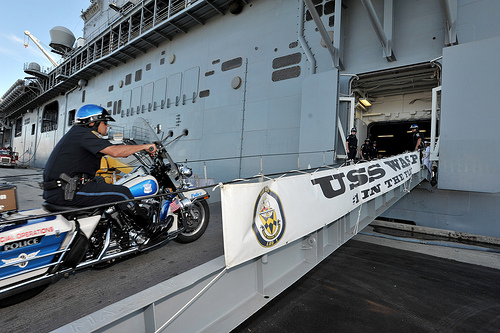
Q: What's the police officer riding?
A: Motorcycle.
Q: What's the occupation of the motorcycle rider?
A: Police officer.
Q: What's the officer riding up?
A: Ramp.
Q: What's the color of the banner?
A: White.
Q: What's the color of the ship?
A: Gray.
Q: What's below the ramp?
A: Water.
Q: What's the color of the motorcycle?
A: Blue and white.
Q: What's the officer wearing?
A: Uniform.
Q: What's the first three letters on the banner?
A: USS.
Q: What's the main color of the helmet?
A: Blue.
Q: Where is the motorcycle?
A: On bridge.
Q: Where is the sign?
A: Bridge's rail.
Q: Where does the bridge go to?
A: Ship.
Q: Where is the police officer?
A: On motorcycle.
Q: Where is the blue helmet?
A: On police officer.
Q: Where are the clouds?
A: Sky.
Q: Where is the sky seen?
A: Over the ship.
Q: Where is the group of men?
A: End of the bridge.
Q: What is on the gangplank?
A: A police motorcycle.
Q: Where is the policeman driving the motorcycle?
A: Onto boat.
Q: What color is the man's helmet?
A: Blue.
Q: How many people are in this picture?
A: 1.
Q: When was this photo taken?
A: Daytime.